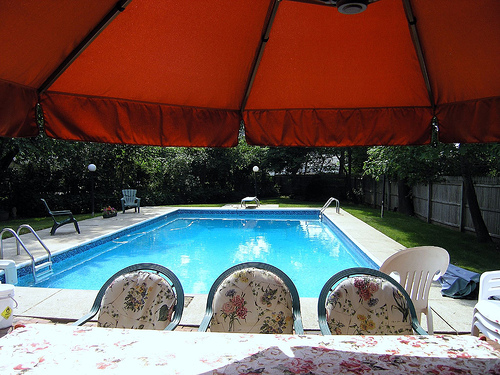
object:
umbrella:
[0, 0, 499, 147]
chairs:
[70, 262, 185, 331]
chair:
[39, 197, 82, 236]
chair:
[378, 245, 451, 335]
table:
[0, 321, 499, 373]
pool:
[0, 208, 382, 298]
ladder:
[0, 223, 55, 285]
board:
[240, 194, 262, 208]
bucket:
[0, 282, 20, 329]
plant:
[100, 205, 116, 219]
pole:
[87, 163, 98, 218]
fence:
[204, 178, 494, 203]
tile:
[179, 209, 321, 215]